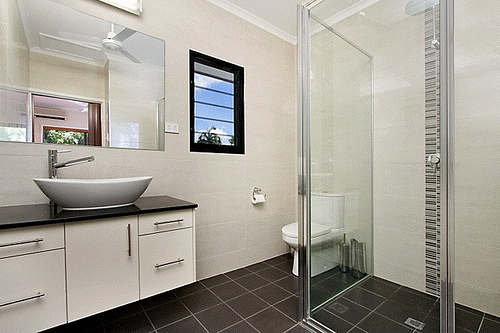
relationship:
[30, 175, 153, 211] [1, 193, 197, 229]
sink on top of counter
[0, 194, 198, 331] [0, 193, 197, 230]
vanity below top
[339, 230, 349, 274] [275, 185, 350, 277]
toiletbrush holder next to toilet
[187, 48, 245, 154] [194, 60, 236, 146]
frame surrounds window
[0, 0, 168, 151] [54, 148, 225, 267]
mirror above sink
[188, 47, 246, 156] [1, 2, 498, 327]
window in bathroom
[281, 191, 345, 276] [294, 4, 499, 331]
toilet next to shower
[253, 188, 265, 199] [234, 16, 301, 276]
holder on wall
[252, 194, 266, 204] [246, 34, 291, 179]
toilet paper hanging from wall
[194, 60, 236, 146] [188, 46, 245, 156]
window has black trim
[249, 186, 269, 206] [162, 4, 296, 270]
toilet paper on wall